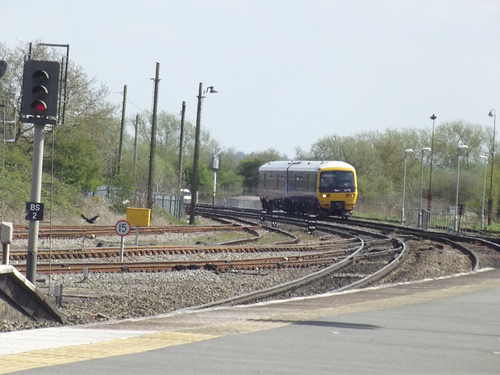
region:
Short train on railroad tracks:
[265, 159, 358, 215]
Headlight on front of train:
[320, 192, 333, 200]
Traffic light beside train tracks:
[17, 54, 58, 286]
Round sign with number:
[112, 219, 132, 236]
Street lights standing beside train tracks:
[402, 109, 494, 233]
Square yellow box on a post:
[125, 207, 153, 226]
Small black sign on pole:
[23, 199, 45, 221]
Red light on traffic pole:
[25, 99, 51, 114]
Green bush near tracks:
[32, 127, 111, 189]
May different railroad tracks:
[21, 219, 498, 293]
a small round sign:
[108, 218, 133, 255]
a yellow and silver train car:
[287, 158, 363, 213]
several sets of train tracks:
[64, 215, 449, 260]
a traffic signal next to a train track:
[14, 46, 68, 139]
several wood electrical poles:
[103, 75, 223, 203]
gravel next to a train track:
[161, 260, 308, 303]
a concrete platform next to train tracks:
[234, 274, 474, 369]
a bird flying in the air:
[78, 210, 108, 228]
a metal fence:
[415, 210, 467, 231]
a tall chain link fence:
[140, 184, 180, 214]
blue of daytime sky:
[0, 2, 496, 154]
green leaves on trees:
[42, 118, 99, 188]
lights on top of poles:
[400, 145, 489, 231]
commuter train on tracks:
[258, 160, 359, 214]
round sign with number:
[116, 219, 132, 261]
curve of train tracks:
[166, 205, 489, 311]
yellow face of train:
[317, 163, 357, 209]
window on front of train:
[319, 169, 353, 189]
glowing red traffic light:
[20, 59, 59, 123]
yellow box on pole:
[129, 206, 151, 242]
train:
[241, 139, 371, 241]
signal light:
[18, 41, 78, 128]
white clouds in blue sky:
[348, 31, 416, 79]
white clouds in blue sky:
[438, 35, 488, 70]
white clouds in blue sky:
[325, 36, 377, 90]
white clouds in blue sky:
[248, 26, 323, 83]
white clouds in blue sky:
[225, 58, 303, 123]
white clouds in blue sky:
[168, 3, 233, 51]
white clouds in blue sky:
[97, 15, 162, 52]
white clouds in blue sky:
[330, 9, 485, 69]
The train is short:
[248, 154, 363, 226]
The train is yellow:
[247, 150, 364, 228]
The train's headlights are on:
[311, 156, 361, 218]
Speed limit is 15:
[111, 218, 133, 261]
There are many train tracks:
[59, 199, 496, 290]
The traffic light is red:
[20, 55, 60, 125]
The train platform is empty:
[6, 150, 496, 372]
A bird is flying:
[78, 205, 105, 230]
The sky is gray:
[0, 0, 498, 157]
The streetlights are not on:
[384, 101, 496, 231]